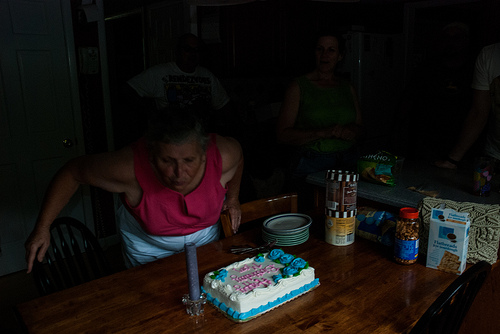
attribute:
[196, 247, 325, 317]
cake — blue, white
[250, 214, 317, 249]
plates — small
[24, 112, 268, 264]
woman — old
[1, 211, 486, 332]
table — brown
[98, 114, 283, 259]
person — wearing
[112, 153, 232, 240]
shirt — white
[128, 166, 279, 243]
top — pink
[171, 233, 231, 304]
candle — blowing out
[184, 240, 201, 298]
candle — large, blue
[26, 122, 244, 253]
woman — old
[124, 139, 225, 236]
shirt — red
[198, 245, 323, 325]
cake — large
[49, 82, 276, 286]
woman — old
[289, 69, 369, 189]
top — green, sleeveless